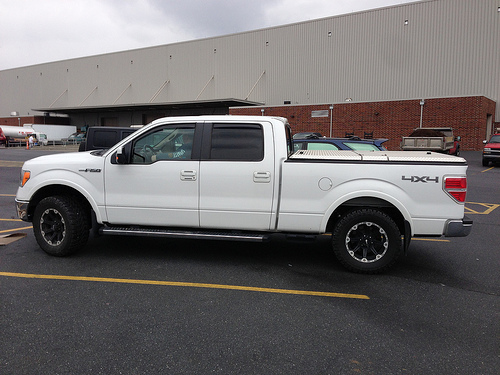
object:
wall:
[306, 33, 489, 83]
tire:
[33, 193, 90, 255]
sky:
[0, 0, 422, 70]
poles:
[77, 86, 97, 106]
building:
[0, 0, 499, 151]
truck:
[399, 128, 461, 156]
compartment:
[317, 177, 333, 191]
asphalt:
[311, 280, 475, 364]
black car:
[79, 125, 181, 162]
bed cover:
[309, 151, 376, 156]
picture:
[0, 0, 498, 372]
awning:
[31, 98, 264, 112]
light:
[445, 177, 467, 203]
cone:
[27, 142, 29, 150]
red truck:
[482, 133, 499, 167]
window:
[210, 128, 263, 159]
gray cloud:
[280, 9, 309, 21]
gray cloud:
[318, 2, 345, 18]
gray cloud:
[125, 2, 149, 26]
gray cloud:
[63, 7, 90, 38]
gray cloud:
[8, 21, 44, 51]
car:
[14, 115, 474, 269]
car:
[291, 131, 322, 139]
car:
[287, 138, 389, 152]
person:
[151, 132, 194, 163]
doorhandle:
[180, 169, 196, 180]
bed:
[289, 150, 467, 165]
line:
[0, 218, 22, 222]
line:
[0, 193, 16, 196]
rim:
[345, 222, 389, 263]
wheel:
[332, 209, 402, 274]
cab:
[105, 115, 292, 231]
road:
[0, 142, 500, 374]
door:
[103, 123, 200, 227]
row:
[47, 70, 264, 108]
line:
[0, 271, 370, 299]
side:
[36, 154, 439, 231]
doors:
[198, 120, 275, 232]